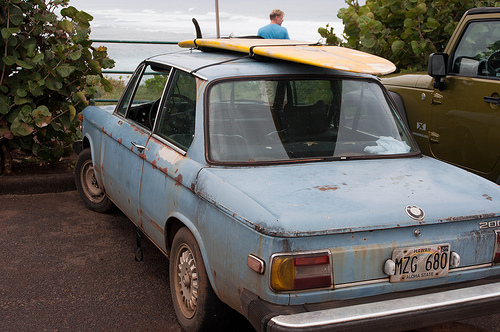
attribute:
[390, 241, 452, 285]
license plate — white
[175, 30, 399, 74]
surfboard — yellow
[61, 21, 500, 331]
car — bmw, baby blue, blue, old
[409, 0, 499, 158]
jeep — parked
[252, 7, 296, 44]
man — standing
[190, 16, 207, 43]
surf fin — black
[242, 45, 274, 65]
straps — black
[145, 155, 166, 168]
spots — brown, rusty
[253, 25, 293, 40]
shirt — blue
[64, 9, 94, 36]
leaves — green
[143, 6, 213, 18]
sky — cloudy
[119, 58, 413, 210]
bmw — old, rusty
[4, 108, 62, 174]
foliage — tall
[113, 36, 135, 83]
fence — steel